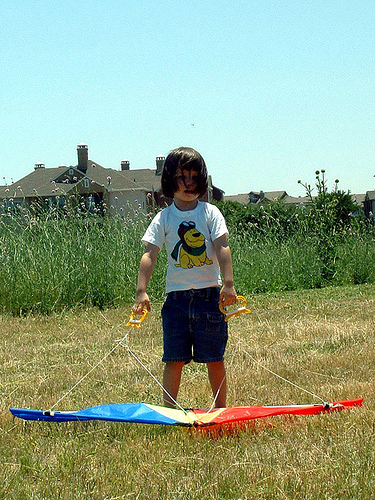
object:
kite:
[14, 400, 363, 430]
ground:
[270, 290, 362, 385]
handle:
[125, 306, 148, 329]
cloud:
[229, 148, 261, 187]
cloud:
[251, 162, 296, 187]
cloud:
[95, 128, 129, 150]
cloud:
[256, 175, 294, 189]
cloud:
[345, 160, 362, 182]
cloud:
[358, 177, 365, 185]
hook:
[218, 295, 251, 322]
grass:
[238, 223, 370, 287]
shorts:
[160, 288, 228, 364]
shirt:
[140, 200, 229, 293]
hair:
[161, 145, 208, 201]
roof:
[7, 164, 170, 185]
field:
[1, 284, 375, 499]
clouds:
[7, 44, 55, 112]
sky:
[1, 0, 369, 211]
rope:
[48, 335, 134, 418]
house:
[0, 142, 226, 233]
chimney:
[76, 144, 88, 171]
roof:
[0, 160, 170, 195]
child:
[132, 145, 238, 408]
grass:
[0, 291, 374, 499]